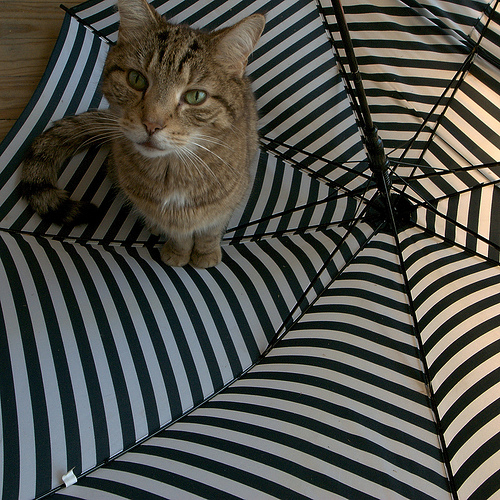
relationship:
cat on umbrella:
[19, 0, 266, 271] [3, 1, 498, 498]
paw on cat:
[157, 232, 192, 268] [19, 0, 266, 271]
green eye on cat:
[128, 69, 148, 92] [18, 32, 278, 271]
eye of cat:
[181, 90, 209, 107] [19, 0, 266, 271]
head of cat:
[96, 0, 266, 161] [19, 0, 266, 271]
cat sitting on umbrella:
[19, 0, 266, 271] [37, 22, 470, 367]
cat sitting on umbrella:
[19, 0, 266, 271] [39, 99, 494, 454]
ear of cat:
[203, 12, 271, 84] [86, 24, 242, 249]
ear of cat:
[110, 3, 163, 38] [19, 0, 266, 271]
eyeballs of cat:
[106, 63, 257, 107] [101, 37, 296, 220]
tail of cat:
[20, 107, 117, 228] [19, 0, 266, 271]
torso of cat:
[112, 81, 258, 227] [19, 0, 266, 271]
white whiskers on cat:
[54, 101, 235, 187] [19, 0, 266, 271]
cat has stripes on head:
[19, 0, 266, 271] [96, 0, 266, 161]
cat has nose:
[88, 37, 308, 282] [137, 112, 175, 140]